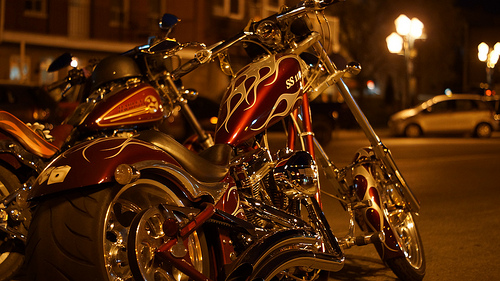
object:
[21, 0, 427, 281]
motorcycle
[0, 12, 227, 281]
motorcycle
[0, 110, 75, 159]
section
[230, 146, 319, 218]
engine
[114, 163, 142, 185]
taillight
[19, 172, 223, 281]
wheel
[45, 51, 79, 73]
mirror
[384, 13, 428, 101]
streetlight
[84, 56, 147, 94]
helmet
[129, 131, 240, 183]
seat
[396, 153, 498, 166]
line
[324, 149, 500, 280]
pavement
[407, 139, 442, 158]
ground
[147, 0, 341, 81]
handlebar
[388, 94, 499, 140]
car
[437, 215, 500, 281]
asphalt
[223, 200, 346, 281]
muffler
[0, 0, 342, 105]
building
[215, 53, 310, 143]
flame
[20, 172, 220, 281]
fat/back tire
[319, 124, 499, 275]
street